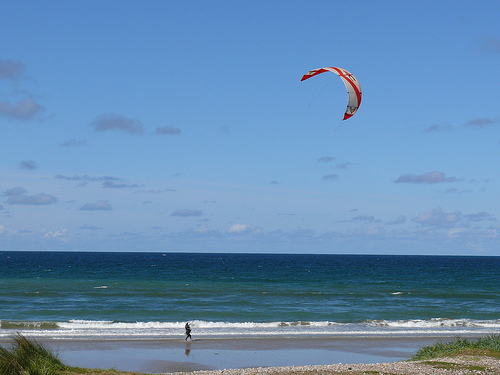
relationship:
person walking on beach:
[184, 318, 194, 343] [0, 333, 478, 373]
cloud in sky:
[151, 124, 183, 139] [1, 0, 499, 255]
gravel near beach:
[160, 353, 498, 375] [0, 333, 478, 373]